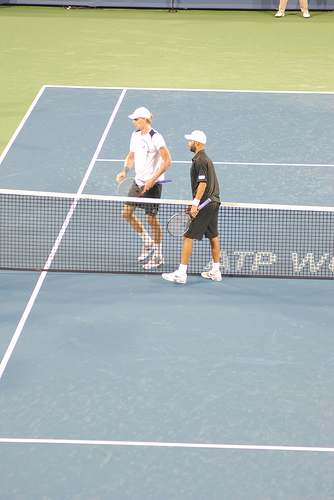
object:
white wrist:
[190, 196, 200, 207]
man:
[160, 128, 222, 283]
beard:
[189, 146, 196, 154]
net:
[0, 188, 333, 280]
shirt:
[127, 129, 168, 187]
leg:
[275, 1, 289, 14]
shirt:
[187, 145, 221, 208]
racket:
[164, 197, 214, 240]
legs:
[297, 0, 308, 13]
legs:
[177, 211, 213, 265]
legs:
[142, 189, 164, 257]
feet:
[272, 9, 286, 19]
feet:
[160, 268, 189, 287]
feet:
[141, 248, 168, 271]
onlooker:
[273, 0, 311, 18]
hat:
[183, 128, 206, 146]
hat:
[125, 106, 153, 120]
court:
[0, 3, 333, 499]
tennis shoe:
[156, 266, 189, 287]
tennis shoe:
[135, 235, 155, 263]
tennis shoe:
[141, 249, 166, 271]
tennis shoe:
[199, 264, 223, 283]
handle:
[155, 173, 172, 185]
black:
[205, 158, 219, 234]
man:
[114, 105, 171, 272]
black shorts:
[124, 178, 162, 218]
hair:
[144, 113, 152, 125]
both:
[116, 105, 225, 284]